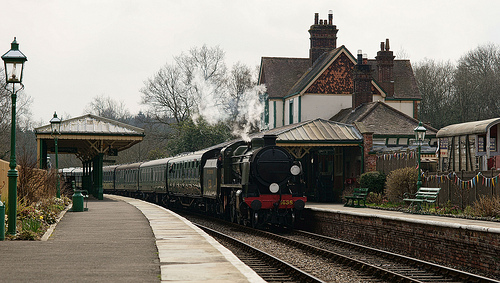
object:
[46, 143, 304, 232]
train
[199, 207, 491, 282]
tracks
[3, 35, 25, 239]
street lamp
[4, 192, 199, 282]
sidewalk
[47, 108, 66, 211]
street lamp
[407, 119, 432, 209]
street lamp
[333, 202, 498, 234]
sidewalk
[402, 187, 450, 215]
bench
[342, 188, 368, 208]
bench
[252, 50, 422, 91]
roof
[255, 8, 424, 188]
building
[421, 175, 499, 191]
flags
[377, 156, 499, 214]
fence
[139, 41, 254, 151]
tree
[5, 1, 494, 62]
sky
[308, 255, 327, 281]
gravel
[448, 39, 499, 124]
trees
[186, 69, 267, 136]
smoke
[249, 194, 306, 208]
frontpiece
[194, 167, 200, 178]
windows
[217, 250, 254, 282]
platform edge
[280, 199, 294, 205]
numbers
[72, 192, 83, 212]
trash can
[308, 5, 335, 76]
chimney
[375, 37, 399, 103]
chimney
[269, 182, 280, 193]
headlights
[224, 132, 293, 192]
engine